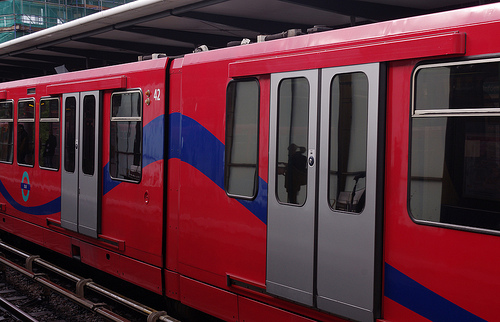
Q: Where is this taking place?
A: In a train yard.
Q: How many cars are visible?
A: Two.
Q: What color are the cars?
A: Red.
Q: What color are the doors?
A: Gray.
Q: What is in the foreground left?
A: The tracks.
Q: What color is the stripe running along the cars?
A: Blue.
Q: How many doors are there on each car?
A: Two.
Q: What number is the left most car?
A: Forty two.